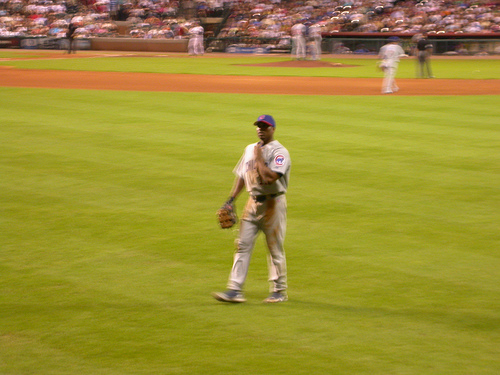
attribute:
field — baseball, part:
[1, 47, 497, 374]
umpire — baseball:
[416, 29, 433, 79]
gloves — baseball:
[212, 207, 237, 231]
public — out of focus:
[330, 0, 495, 36]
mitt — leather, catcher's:
[216, 198, 239, 230]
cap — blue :
[256, 114, 276, 126]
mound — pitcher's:
[238, 41, 330, 82]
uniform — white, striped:
[238, 147, 301, 219]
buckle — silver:
[246, 190, 284, 219]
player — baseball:
[211, 112, 288, 308]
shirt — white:
[233, 139, 288, 204]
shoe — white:
[265, 289, 288, 304]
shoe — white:
[213, 290, 246, 307]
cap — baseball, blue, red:
[251, 109, 281, 133]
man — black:
[63, 15, 82, 60]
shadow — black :
[302, 290, 497, 342]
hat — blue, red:
[252, 114, 283, 131]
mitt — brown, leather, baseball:
[219, 205, 236, 227]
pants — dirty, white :
[225, 194, 290, 294]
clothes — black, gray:
[416, 36, 435, 73]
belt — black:
[245, 185, 285, 200]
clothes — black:
[65, 19, 77, 50]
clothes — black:
[416, 39, 432, 76]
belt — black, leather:
[246, 190, 286, 199]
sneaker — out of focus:
[214, 288, 244, 305]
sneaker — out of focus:
[264, 290, 286, 304]